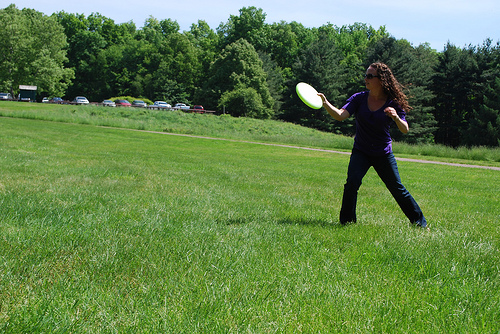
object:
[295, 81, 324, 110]
frisbee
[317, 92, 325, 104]
hand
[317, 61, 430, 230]
girl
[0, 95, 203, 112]
lot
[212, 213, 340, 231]
shadow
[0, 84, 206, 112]
parking lot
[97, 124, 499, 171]
pathway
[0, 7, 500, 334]
park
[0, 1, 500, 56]
sky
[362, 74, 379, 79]
glasses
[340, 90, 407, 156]
shirt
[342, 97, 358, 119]
short sleeve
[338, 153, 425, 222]
pants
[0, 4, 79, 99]
tree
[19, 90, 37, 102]
wall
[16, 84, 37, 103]
building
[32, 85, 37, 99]
side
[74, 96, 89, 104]
car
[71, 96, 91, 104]
car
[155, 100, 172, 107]
car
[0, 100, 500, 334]
grass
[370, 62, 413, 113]
hair